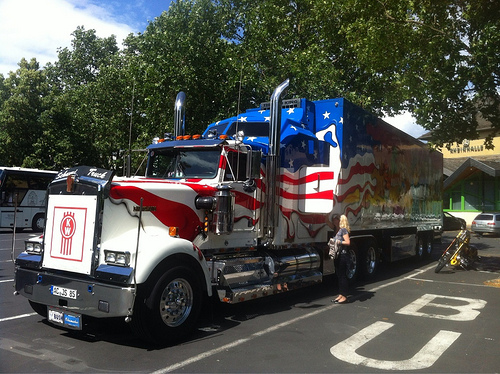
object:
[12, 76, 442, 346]
semi truck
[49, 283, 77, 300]
tag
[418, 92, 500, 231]
building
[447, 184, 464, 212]
pillars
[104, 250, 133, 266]
headlights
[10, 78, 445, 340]
semi-trailer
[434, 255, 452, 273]
tire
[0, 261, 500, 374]
ground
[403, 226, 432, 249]
car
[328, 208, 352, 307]
woman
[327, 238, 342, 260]
something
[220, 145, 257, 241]
door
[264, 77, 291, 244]
exhaust pipe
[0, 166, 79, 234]
bus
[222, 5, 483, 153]
trees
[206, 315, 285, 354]
line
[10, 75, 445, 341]
18 wheeler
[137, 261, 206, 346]
tire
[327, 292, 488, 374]
letters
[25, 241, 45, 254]
headlight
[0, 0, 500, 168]
leaves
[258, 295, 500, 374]
cement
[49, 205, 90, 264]
flag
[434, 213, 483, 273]
motorcycle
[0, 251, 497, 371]
parking lot